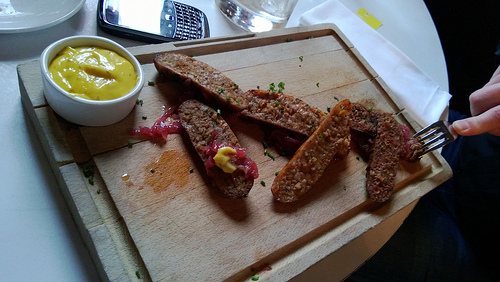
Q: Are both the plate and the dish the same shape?
A: Yes, both the plate and the dish are round.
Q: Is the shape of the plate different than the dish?
A: No, both the plate and the dish are round.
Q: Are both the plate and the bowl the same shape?
A: Yes, both the plate and the bowl are round.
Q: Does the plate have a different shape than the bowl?
A: No, both the plate and the bowl are round.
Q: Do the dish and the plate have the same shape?
A: Yes, both the dish and the plate are round.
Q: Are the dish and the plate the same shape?
A: Yes, both the dish and the plate are round.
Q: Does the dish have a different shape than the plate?
A: No, both the dish and the plate are round.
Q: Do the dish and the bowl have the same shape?
A: Yes, both the dish and the bowl are round.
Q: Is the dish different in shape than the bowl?
A: No, both the dish and the bowl are round.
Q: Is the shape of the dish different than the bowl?
A: No, both the dish and the bowl are round.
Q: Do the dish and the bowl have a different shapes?
A: No, both the dish and the bowl are round.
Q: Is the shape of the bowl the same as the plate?
A: Yes, both the bowl and the plate are round.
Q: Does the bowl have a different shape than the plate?
A: No, both the bowl and the plate are round.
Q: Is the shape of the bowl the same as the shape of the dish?
A: Yes, both the bowl and the dish are round.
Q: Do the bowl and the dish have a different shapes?
A: No, both the bowl and the dish are round.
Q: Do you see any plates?
A: Yes, there is a plate.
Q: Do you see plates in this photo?
A: Yes, there is a plate.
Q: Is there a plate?
A: Yes, there is a plate.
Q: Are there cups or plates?
A: Yes, there is a plate.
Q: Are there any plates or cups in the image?
A: Yes, there is a plate.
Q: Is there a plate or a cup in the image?
A: Yes, there is a plate.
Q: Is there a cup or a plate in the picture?
A: Yes, there is a plate.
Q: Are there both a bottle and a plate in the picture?
A: No, there is a plate but no bottles.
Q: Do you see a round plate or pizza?
A: Yes, there is a round plate.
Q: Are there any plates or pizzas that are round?
A: Yes, the plate is round.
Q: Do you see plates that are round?
A: Yes, there is a round plate.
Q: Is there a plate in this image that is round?
A: Yes, there is a plate that is round.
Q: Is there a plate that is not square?
A: Yes, there is a round plate.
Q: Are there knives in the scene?
A: No, there are no knives.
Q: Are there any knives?
A: No, there are no knives.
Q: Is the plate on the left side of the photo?
A: Yes, the plate is on the left of the image.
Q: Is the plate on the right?
A: No, the plate is on the left of the image.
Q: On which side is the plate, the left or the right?
A: The plate is on the left of the image.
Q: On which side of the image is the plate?
A: The plate is on the left of the image.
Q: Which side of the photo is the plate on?
A: The plate is on the left of the image.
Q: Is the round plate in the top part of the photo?
A: Yes, the plate is in the top of the image.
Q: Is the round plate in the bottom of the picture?
A: No, the plate is in the top of the image.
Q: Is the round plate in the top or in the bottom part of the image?
A: The plate is in the top of the image.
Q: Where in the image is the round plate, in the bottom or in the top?
A: The plate is in the top of the image.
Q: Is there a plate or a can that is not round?
A: No, there is a plate but it is round.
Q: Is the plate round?
A: Yes, the plate is round.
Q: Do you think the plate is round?
A: Yes, the plate is round.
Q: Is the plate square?
A: No, the plate is round.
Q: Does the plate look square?
A: No, the plate is round.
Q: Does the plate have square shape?
A: No, the plate is round.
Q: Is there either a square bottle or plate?
A: No, there is a plate but it is round.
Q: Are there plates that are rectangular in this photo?
A: No, there is a plate but it is round.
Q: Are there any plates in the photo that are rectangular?
A: No, there is a plate but it is round.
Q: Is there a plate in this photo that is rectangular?
A: No, there is a plate but it is round.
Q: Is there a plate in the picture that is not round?
A: No, there is a plate but it is round.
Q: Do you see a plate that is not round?
A: No, there is a plate but it is round.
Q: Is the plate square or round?
A: The plate is round.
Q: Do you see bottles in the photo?
A: No, there are no bottles.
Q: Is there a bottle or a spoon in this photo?
A: No, there are no bottles or spoons.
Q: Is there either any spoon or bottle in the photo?
A: No, there are no bottles or spoons.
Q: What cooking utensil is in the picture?
A: The cooking utensil is a cutting board.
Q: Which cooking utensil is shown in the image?
A: The cooking utensil is a cutting board.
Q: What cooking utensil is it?
A: The cooking utensil is a cutting board.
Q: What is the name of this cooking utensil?
A: This is a cutting board.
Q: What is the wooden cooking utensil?
A: The cooking utensil is a cutting board.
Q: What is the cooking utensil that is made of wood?
A: The cooking utensil is a cutting board.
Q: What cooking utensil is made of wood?
A: The cooking utensil is a cutting board.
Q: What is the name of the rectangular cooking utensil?
A: The cooking utensil is a cutting board.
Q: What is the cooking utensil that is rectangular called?
A: The cooking utensil is a cutting board.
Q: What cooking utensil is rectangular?
A: The cooking utensil is a cutting board.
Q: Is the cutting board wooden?
A: Yes, the cutting board is wooden.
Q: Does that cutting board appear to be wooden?
A: Yes, the cutting board is wooden.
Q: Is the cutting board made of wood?
A: Yes, the cutting board is made of wood.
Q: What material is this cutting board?
A: The cutting board is made of wood.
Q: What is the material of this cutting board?
A: The cutting board is made of wood.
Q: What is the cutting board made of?
A: The cutting board is made of wood.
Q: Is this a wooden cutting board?
A: Yes, this is a wooden cutting board.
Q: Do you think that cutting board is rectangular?
A: Yes, the cutting board is rectangular.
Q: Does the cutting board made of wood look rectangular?
A: Yes, the cutting board is rectangular.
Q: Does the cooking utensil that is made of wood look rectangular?
A: Yes, the cutting board is rectangular.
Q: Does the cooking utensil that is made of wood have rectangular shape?
A: Yes, the cutting board is rectangular.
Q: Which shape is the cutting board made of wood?
A: The cutting board is rectangular.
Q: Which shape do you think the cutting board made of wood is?
A: The cutting board is rectangular.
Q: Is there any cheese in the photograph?
A: No, there is no cheese.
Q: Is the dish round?
A: Yes, the dish is round.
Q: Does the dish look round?
A: Yes, the dish is round.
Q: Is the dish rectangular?
A: No, the dish is round.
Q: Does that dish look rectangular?
A: No, the dish is round.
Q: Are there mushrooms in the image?
A: No, there are no mushrooms.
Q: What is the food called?
A: The food is a sausage.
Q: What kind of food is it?
A: The food is a sausage.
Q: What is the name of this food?
A: This is a sausage.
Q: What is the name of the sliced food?
A: The food is a sausage.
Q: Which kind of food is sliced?
A: The food is a sausage.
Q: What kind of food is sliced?
A: The food is a sausage.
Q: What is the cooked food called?
A: The food is a sausage.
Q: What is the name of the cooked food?
A: The food is a sausage.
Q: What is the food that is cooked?
A: The food is a sausage.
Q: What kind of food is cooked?
A: The food is a sausage.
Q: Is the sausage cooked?
A: Yes, the sausage is cooked.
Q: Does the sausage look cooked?
A: Yes, the sausage is cooked.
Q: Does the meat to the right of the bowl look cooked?
A: Yes, the sausage is cooked.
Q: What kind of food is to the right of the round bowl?
A: The food is a sausage.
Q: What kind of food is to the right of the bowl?
A: The food is a sausage.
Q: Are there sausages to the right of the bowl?
A: Yes, there is a sausage to the right of the bowl.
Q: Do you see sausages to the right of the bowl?
A: Yes, there is a sausage to the right of the bowl.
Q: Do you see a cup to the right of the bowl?
A: No, there is a sausage to the right of the bowl.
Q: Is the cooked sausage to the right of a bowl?
A: Yes, the sausage is to the right of a bowl.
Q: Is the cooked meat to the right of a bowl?
A: Yes, the sausage is to the right of a bowl.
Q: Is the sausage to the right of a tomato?
A: No, the sausage is to the right of a bowl.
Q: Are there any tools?
A: No, there are no tools.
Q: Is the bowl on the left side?
A: Yes, the bowl is on the left of the image.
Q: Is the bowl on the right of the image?
A: No, the bowl is on the left of the image.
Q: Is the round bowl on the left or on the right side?
A: The bowl is on the left of the image.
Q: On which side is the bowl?
A: The bowl is on the left of the image.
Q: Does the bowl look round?
A: Yes, the bowl is round.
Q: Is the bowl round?
A: Yes, the bowl is round.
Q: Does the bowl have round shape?
A: Yes, the bowl is round.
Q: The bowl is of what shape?
A: The bowl is round.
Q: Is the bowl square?
A: No, the bowl is round.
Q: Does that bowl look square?
A: No, the bowl is round.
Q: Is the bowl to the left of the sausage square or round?
A: The bowl is round.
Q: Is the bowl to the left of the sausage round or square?
A: The bowl is round.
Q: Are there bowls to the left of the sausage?
A: Yes, there is a bowl to the left of the sausage.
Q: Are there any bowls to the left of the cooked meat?
A: Yes, there is a bowl to the left of the sausage.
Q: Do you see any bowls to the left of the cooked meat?
A: Yes, there is a bowl to the left of the sausage.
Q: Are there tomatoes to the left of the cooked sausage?
A: No, there is a bowl to the left of the sausage.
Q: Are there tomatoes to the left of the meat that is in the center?
A: No, there is a bowl to the left of the sausage.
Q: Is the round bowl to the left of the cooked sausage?
A: Yes, the bowl is to the left of the sausage.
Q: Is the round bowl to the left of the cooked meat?
A: Yes, the bowl is to the left of the sausage.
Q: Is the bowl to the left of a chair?
A: No, the bowl is to the left of the sausage.